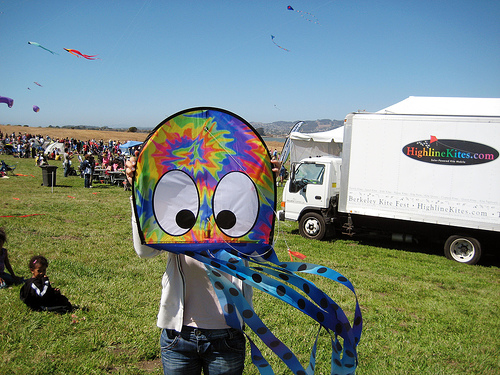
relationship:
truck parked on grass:
[282, 110, 494, 258] [380, 260, 489, 367]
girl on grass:
[18, 252, 74, 313] [0, 153, 498, 371]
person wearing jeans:
[122, 146, 281, 373] [146, 321, 252, 373]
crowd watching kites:
[14, 133, 115, 179] [1, 5, 324, 117]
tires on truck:
[300, 194, 496, 268] [265, 95, 483, 282]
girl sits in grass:
[18, 252, 74, 313] [0, 153, 498, 371]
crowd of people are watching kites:
[14, 133, 115, 179] [12, 28, 112, 90]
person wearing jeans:
[122, 146, 281, 373] [159, 325, 248, 374]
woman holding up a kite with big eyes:
[125, 142, 250, 373] [147, 169, 261, 239]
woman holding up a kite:
[125, 142, 250, 373] [127, 102, 285, 267]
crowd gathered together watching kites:
[14, 133, 115, 179] [0, 2, 297, 120]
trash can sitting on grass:
[31, 161, 61, 183] [24, 188, 108, 255]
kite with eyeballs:
[128, 106, 363, 373] [148, 163, 263, 245]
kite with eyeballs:
[260, 31, 292, 57] [148, 163, 263, 245]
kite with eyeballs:
[58, 39, 100, 66] [148, 163, 263, 245]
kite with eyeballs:
[18, 32, 58, 59] [148, 163, 263, 245]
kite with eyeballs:
[277, 3, 317, 19] [148, 163, 263, 245]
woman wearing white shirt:
[125, 142, 250, 373] [130, 192, 252, 329]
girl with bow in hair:
[18, 252, 74, 313] [36, 249, 50, 265]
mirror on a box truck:
[284, 162, 300, 192] [236, 66, 497, 299]